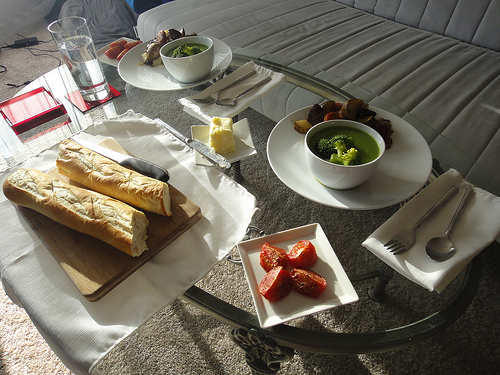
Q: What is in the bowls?
A: Broccoli.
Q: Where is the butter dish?
A: Middle of table.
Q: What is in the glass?
A: Clear liquid - water.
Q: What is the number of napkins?
A: 3.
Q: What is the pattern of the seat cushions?
A: Stripe.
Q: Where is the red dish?
A: Top left.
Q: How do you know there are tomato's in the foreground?
A: Shape and color.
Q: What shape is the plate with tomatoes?
A: Sqaure.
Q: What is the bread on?
A: Wood cutting board.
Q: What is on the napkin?
A: Silverware.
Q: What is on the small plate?
A: Tomatoes.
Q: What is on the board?
A: Bread.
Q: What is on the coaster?
A: Water.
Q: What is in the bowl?
A: Green soup.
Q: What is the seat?
A: White.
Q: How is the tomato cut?
A: In fourths.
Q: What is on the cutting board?
A: A knife.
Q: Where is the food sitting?
A: Table.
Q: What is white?
A: Napkin.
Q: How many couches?
A: One.